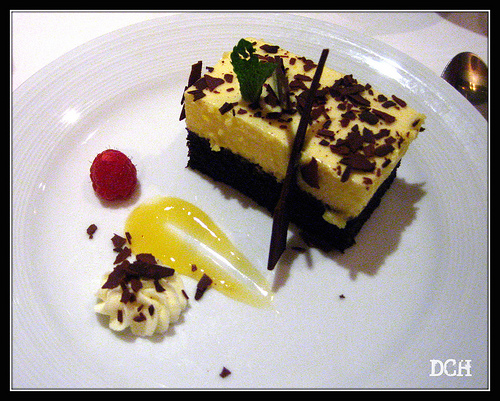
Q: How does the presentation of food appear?
A: Gourmet.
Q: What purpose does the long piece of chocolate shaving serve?
A: It is an interesting garnish and tasty, too.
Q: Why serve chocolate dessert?
A: Dessert is a pleasant way to finish a meal.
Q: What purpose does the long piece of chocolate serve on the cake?
A: The chocolate spear adds textural contrast to the dish.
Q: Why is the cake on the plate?
A: The plate provides a negative space that makes the dish visually interesting.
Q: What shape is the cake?
A: Rectangular.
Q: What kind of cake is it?
A: Chocolate.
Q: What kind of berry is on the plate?
A: Raspberry.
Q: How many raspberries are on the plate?
A: One.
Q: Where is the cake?
A: On a plate.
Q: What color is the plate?
A: White.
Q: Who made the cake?
A: A chef.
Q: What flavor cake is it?
A: Chocolate.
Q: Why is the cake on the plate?
A: For the people.